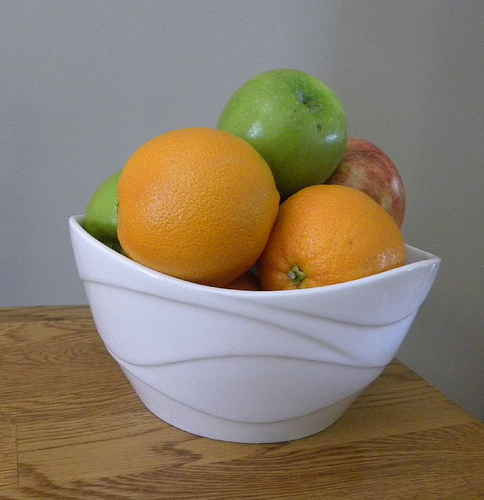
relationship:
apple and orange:
[213, 71, 349, 197] [121, 123, 278, 285]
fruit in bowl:
[109, 73, 415, 290] [72, 196, 434, 454]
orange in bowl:
[121, 123, 278, 285] [72, 196, 434, 454]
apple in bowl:
[229, 62, 353, 189] [72, 196, 434, 454]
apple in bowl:
[346, 131, 421, 237] [72, 196, 434, 454]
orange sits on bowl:
[121, 123, 278, 285] [72, 196, 434, 454]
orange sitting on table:
[121, 123, 278, 285] [2, 285, 480, 498]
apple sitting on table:
[213, 71, 349, 197] [2, 285, 480, 498]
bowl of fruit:
[72, 196, 434, 454] [109, 73, 415, 290]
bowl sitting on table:
[72, 196, 434, 454] [2, 285, 480, 498]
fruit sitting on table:
[109, 73, 415, 290] [2, 285, 480, 498]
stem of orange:
[280, 259, 314, 288] [121, 123, 278, 285]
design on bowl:
[74, 268, 409, 434] [72, 196, 434, 454]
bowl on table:
[72, 196, 434, 454] [2, 285, 480, 498]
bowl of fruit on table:
[72, 196, 434, 454] [2, 285, 480, 498]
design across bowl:
[74, 268, 409, 434] [72, 196, 434, 454]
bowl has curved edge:
[72, 196, 434, 454] [56, 211, 282, 361]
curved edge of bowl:
[56, 211, 282, 361] [72, 196, 434, 454]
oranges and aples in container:
[109, 73, 415, 290] [72, 196, 434, 454]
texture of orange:
[169, 175, 242, 243] [121, 123, 278, 285]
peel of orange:
[146, 163, 221, 237] [121, 123, 278, 285]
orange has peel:
[121, 123, 278, 285] [146, 163, 221, 237]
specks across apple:
[277, 81, 296, 115] [229, 62, 353, 189]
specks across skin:
[277, 81, 296, 115] [247, 100, 299, 140]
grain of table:
[7, 316, 91, 497] [2, 285, 480, 498]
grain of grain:
[7, 316, 91, 497] [7, 316, 91, 497]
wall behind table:
[9, 13, 168, 146] [2, 285, 480, 498]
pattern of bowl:
[74, 268, 409, 434] [72, 196, 434, 454]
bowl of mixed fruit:
[72, 196, 434, 454] [215, 62, 395, 284]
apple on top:
[229, 62, 353, 189] [182, 66, 384, 177]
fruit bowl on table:
[72, 196, 434, 454] [2, 285, 480, 498]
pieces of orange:
[109, 73, 415, 290] [121, 123, 278, 285]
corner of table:
[2, 285, 480, 498] [0, 429, 462, 497]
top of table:
[2, 285, 480, 498] [7, 415, 468, 497]